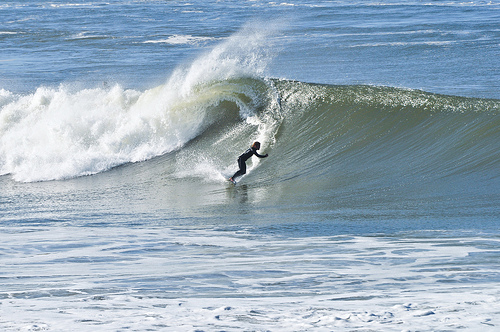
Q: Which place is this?
A: It is an ocean.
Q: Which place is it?
A: It is an ocean.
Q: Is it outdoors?
A: Yes, it is outdoors.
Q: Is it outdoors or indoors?
A: It is outdoors.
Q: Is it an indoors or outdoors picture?
A: It is outdoors.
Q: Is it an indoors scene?
A: No, it is outdoors.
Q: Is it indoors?
A: No, it is outdoors.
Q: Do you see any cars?
A: No, there are no cars.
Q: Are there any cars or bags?
A: No, there are no cars or bags.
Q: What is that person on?
A: The person is on the surf board.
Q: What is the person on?
A: The person is on the surf board.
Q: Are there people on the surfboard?
A: Yes, there is a person on the surfboard.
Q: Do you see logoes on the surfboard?
A: No, there is a person on the surfboard.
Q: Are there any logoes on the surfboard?
A: No, there is a person on the surfboard.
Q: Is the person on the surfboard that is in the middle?
A: Yes, the person is on the surfboard.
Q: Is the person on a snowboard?
A: No, the person is on the surfboard.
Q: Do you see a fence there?
A: No, there are no fences.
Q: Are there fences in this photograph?
A: No, there are no fences.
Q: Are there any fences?
A: No, there are no fences.